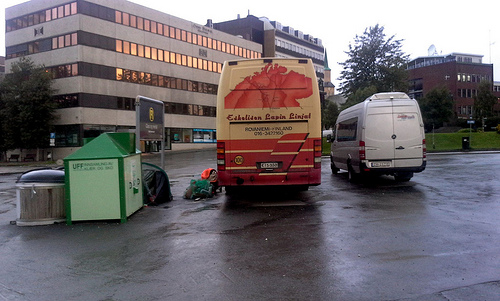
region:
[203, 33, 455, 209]
A white van parked next to the bus.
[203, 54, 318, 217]
A bus parked in the parking lot.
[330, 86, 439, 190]
A white van parked in the parking lot.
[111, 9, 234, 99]
The building has windows.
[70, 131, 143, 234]
A green pick up bin in the parking lot.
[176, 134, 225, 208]
Bags are next to the bus.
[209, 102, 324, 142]
The bus has red writing on the back.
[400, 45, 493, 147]
The building is made of bricks.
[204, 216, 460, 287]
The ground is wet.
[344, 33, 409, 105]
A tree is next to the building.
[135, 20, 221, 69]
windows on office building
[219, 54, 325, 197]
back of parked bus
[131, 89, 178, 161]
sign on metal poles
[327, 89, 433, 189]
white van parked in lot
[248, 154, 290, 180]
license plate on bus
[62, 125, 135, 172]
top of green bin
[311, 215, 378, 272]
wet surface of asphalt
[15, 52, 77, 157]
tree on side of building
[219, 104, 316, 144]
words on back of bus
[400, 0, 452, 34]
white cloud cover in sky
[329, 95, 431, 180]
White van with dark windows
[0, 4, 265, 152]
Large building with windows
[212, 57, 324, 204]
red and tan bus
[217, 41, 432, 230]
bus next to van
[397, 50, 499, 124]
Red brick office building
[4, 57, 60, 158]
large green tree beside building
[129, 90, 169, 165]
yellow and black sign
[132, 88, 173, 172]
yellow and black sign in front of building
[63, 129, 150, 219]
Green recycle container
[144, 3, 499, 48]
overcast sky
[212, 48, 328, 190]
the big bus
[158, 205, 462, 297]
the wet pavement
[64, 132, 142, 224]
the small green container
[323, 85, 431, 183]
the small white van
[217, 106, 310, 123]
the red words on the back of the bus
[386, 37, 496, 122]
the red brick building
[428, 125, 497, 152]
the short green grass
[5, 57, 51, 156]
the green tree near the building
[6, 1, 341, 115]
the buildings lined up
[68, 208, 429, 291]
the water on the ground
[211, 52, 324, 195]
the back of a tan and red bus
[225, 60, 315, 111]
red design on a tan bus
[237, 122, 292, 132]
black text on the back of a bus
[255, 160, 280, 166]
license plate on a bus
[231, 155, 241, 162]
circle label on the back of a bus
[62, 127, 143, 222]
green bin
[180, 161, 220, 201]
items on a wet ground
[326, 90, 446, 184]
parked white vehicle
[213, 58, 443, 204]
two parked vehicles on a white ground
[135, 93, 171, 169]
brown sign